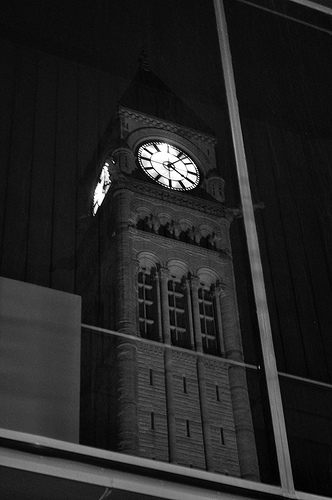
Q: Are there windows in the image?
A: Yes, there is a window.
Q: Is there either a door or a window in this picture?
A: Yes, there is a window.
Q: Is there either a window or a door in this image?
A: Yes, there is a window.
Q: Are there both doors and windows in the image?
A: No, there is a window but no doors.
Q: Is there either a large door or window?
A: Yes, there is a large window.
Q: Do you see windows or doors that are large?
A: Yes, the window is large.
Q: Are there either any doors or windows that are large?
A: Yes, the window is large.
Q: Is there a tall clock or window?
A: Yes, there is a tall window.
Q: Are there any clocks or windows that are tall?
A: Yes, the window is tall.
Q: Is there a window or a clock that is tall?
A: Yes, the window is tall.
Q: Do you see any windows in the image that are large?
A: Yes, there is a large window.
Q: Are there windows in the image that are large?
A: Yes, there is a window that is large.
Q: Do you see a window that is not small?
A: Yes, there is a large window.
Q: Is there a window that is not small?
A: Yes, there is a large window.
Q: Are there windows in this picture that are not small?
A: Yes, there is a large window.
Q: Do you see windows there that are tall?
A: Yes, there is a tall window.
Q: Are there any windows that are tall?
A: Yes, there is a window that is tall.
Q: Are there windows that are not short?
A: Yes, there is a tall window.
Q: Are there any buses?
A: No, there are no buses.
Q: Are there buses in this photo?
A: No, there are no buses.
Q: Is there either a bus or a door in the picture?
A: No, there are no buses or doors.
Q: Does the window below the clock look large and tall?
A: Yes, the window is large and tall.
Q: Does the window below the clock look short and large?
A: No, the window is large but tall.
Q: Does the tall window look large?
A: Yes, the window is large.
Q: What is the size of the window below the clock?
A: The window is large.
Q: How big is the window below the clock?
A: The window is large.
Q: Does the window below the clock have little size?
A: No, the window is large.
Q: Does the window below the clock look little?
A: No, the window is large.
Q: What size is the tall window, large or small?
A: The window is large.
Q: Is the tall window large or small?
A: The window is large.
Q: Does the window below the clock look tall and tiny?
A: No, the window is tall but large.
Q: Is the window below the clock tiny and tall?
A: No, the window is tall but large.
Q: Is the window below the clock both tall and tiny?
A: No, the window is tall but large.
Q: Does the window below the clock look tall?
A: Yes, the window is tall.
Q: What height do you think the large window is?
A: The window is tall.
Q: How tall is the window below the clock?
A: The window is tall.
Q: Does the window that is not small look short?
A: No, the window is tall.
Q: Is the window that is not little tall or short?
A: The window is tall.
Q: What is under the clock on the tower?
A: The window is under the clock.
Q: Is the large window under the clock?
A: Yes, the window is under the clock.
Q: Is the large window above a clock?
A: No, the window is under a clock.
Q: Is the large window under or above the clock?
A: The window is under the clock.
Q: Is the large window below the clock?
A: Yes, the window is below the clock.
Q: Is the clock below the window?
A: No, the window is below the clock.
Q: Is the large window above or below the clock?
A: The window is below the clock.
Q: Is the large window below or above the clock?
A: The window is below the clock.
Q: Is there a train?
A: No, there are no trains.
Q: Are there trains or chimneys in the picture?
A: No, there are no trains or chimneys.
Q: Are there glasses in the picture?
A: No, there are no glasses.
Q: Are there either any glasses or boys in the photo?
A: No, there are no glasses or boys.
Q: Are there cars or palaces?
A: No, there are no cars or palaces.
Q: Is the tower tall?
A: Yes, the tower is tall.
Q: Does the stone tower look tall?
A: Yes, the tower is tall.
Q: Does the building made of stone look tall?
A: Yes, the tower is tall.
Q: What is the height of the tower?
A: The tower is tall.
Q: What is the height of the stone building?
A: The tower is tall.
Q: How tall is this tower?
A: The tower is tall.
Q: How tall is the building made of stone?
A: The tower is tall.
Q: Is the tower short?
A: No, the tower is tall.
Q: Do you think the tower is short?
A: No, the tower is tall.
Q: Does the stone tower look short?
A: No, the tower is tall.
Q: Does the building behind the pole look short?
A: No, the tower is tall.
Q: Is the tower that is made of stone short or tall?
A: The tower is tall.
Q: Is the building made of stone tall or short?
A: The tower is tall.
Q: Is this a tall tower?
A: Yes, this is a tall tower.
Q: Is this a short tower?
A: No, this is a tall tower.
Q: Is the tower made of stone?
A: Yes, the tower is made of stone.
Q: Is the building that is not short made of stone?
A: Yes, the tower is made of stone.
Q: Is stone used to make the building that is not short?
A: Yes, the tower is made of stone.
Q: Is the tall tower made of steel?
A: No, the tower is made of stone.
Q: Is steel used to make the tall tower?
A: No, the tower is made of stone.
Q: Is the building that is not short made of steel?
A: No, the tower is made of stone.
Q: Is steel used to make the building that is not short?
A: No, the tower is made of stone.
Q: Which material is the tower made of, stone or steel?
A: The tower is made of stone.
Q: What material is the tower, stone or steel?
A: The tower is made of stone.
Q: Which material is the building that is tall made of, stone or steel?
A: The tower is made of stone.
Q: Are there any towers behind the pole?
A: Yes, there is a tower behind the pole.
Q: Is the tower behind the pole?
A: Yes, the tower is behind the pole.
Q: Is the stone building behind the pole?
A: Yes, the tower is behind the pole.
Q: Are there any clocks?
A: Yes, there is a clock.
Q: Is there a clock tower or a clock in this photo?
A: Yes, there is a clock.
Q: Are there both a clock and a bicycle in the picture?
A: No, there is a clock but no bicycles.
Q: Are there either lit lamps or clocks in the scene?
A: Yes, there is a lit clock.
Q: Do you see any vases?
A: No, there are no vases.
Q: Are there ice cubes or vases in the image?
A: No, there are no vases or ice cubes.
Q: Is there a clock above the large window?
A: Yes, there is a clock above the window.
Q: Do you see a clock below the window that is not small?
A: No, the clock is above the window.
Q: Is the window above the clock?
A: No, the clock is above the window.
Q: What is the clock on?
A: The clock is on the tower.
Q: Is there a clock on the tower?
A: Yes, there is a clock on the tower.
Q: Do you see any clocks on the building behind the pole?
A: Yes, there is a clock on the tower.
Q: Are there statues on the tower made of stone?
A: No, there is a clock on the tower.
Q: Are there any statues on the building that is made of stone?
A: No, there is a clock on the tower.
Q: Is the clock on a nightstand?
A: No, the clock is on the tower.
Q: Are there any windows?
A: Yes, there is a window.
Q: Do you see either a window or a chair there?
A: Yes, there is a window.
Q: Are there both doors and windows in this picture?
A: No, there is a window but no doors.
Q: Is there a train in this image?
A: No, there are no trains.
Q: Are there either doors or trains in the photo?
A: No, there are no trains or doors.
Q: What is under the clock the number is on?
A: The window is under the clock.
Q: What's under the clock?
A: The window is under the clock.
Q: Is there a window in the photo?
A: Yes, there is a window.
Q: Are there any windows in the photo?
A: Yes, there is a window.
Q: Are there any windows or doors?
A: Yes, there is a window.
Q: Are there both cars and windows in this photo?
A: No, there is a window but no cars.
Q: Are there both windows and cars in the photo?
A: No, there is a window but no cars.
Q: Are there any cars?
A: No, there are no cars.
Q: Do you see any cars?
A: No, there are no cars.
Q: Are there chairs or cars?
A: No, there are no cars or chairs.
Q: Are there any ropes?
A: No, there are no ropes.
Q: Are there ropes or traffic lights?
A: No, there are no ropes or traffic lights.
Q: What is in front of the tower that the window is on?
A: The pole is in front of the tower.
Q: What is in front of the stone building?
A: The pole is in front of the tower.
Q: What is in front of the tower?
A: The pole is in front of the tower.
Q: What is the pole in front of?
A: The pole is in front of the tower.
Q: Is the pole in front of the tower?
A: Yes, the pole is in front of the tower.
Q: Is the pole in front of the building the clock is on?
A: Yes, the pole is in front of the tower.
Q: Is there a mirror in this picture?
A: No, there are no mirrors.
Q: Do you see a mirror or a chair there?
A: No, there are no mirrors or chairs.